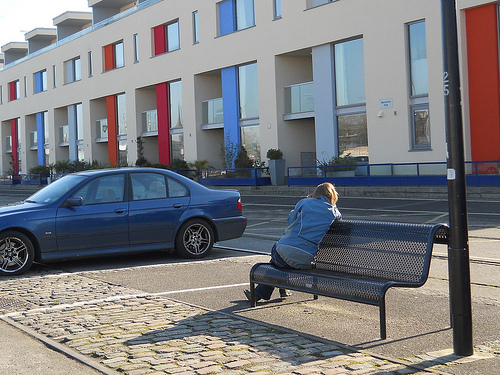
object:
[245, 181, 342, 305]
woman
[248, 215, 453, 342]
bench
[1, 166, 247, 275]
car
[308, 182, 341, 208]
hair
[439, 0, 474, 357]
pole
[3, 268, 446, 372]
ground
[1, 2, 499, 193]
building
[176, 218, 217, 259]
wheel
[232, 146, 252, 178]
bush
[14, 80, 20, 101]
window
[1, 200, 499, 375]
parking lot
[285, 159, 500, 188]
fence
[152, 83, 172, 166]
streak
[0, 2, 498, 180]
wall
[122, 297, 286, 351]
shadow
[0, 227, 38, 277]
wheel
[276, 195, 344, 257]
jacket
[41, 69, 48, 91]
window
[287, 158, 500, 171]
railing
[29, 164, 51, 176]
shrubbery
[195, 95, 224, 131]
balcony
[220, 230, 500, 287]
sidewalk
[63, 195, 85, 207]
mirror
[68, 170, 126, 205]
window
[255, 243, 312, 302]
jeans